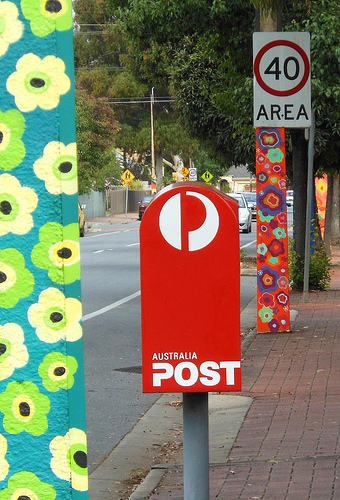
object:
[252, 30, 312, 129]
sign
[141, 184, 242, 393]
sign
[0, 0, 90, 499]
post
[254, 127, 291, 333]
post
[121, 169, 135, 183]
street sign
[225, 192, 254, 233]
car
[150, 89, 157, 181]
pole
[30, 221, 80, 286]
flower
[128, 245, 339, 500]
side walk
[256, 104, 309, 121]
letters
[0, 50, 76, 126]
print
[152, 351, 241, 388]
letters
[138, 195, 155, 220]
car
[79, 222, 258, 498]
street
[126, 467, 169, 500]
curb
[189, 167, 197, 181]
sign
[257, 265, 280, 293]
flower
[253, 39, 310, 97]
circle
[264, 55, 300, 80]
number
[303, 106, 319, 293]
pole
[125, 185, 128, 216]
post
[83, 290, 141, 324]
paint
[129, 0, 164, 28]
leaves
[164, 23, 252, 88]
branches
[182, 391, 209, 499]
post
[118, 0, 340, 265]
tree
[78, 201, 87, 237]
car